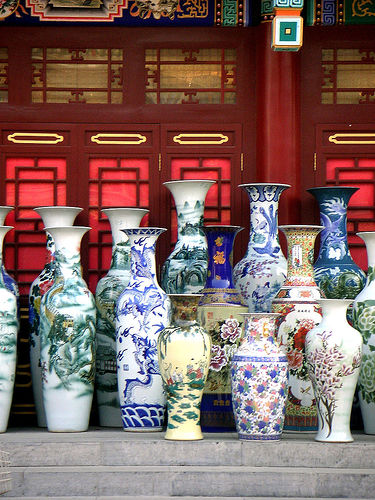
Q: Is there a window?
A: Yes, there are windows.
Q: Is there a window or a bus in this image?
A: Yes, there are windows.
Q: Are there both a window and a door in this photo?
A: Yes, there are both a window and a door.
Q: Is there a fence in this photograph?
A: No, there are no fences.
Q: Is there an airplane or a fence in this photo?
A: No, there are no fences or airplanes.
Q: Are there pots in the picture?
A: No, there are no pots.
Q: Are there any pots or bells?
A: No, there are no pots or bells.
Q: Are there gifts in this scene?
A: No, there are no gifts.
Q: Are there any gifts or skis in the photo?
A: No, there are no gifts or skis.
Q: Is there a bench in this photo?
A: No, there are no benches.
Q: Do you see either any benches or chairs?
A: No, there are no benches or chairs.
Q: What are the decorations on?
A: The decorations are on the vase.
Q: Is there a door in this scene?
A: Yes, there is a door.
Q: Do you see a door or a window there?
A: Yes, there is a door.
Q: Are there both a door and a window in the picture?
A: Yes, there are both a door and a window.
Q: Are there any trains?
A: No, there are no trains.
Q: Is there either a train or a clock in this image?
A: No, there are no trains or clocks.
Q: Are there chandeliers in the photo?
A: No, there are no chandeliers.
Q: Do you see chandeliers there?
A: No, there are no chandeliers.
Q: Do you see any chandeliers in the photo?
A: No, there are no chandeliers.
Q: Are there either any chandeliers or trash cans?
A: No, there are no chandeliers or trash cans.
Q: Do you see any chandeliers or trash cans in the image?
A: No, there are no chandeliers or trash cans.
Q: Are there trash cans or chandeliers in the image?
A: No, there are no chandeliers or trash cans.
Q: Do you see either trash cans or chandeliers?
A: No, there are no chandeliers or trash cans.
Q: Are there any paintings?
A: No, there are no paintings.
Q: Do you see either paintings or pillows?
A: No, there are no paintings or pillows.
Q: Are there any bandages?
A: No, there are no bandages.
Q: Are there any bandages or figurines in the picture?
A: No, there are no bandages or figurines.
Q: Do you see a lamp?
A: No, there are no lamps.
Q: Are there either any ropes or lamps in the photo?
A: No, there are no lamps or ropes.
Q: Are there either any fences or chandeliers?
A: No, there are no chandeliers or fences.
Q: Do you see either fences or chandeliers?
A: No, there are no chandeliers or fences.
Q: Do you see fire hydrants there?
A: No, there are no fire hydrants.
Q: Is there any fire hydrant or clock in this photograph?
A: No, there are no fire hydrants or clocks.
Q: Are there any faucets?
A: No, there are no faucets.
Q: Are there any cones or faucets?
A: No, there are no faucets or cones.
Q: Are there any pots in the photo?
A: No, there are no pots.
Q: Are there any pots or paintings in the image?
A: No, there are no pots or paintings.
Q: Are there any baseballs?
A: No, there are no baseballs.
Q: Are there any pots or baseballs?
A: No, there are no baseballs or pots.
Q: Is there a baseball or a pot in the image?
A: No, there are no baseballs or pots.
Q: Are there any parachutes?
A: No, there are no parachutes.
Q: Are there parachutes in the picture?
A: No, there are no parachutes.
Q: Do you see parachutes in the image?
A: No, there are no parachutes.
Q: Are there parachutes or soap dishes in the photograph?
A: No, there are no parachutes or soap dishes.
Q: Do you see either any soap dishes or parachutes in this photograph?
A: No, there are no parachutes or soap dishes.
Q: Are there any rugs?
A: No, there are no rugs.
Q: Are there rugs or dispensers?
A: No, there are no rugs or dispensers.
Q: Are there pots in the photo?
A: No, there are no pots.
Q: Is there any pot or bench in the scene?
A: No, there are no pots or benches.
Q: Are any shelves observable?
A: No, there are no shelves.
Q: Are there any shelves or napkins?
A: No, there are no shelves or napkins.